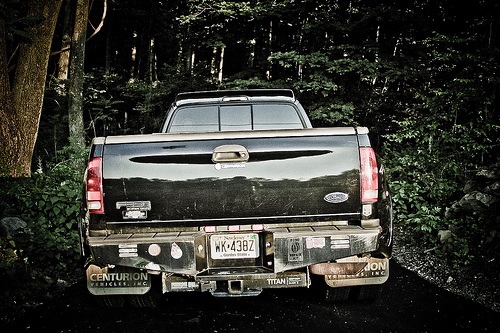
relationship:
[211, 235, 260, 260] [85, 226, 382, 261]
license plate on bumper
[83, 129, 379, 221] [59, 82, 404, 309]
tailgate on truck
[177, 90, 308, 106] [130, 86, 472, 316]
rack on top of truck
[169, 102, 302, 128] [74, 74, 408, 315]
back window on ford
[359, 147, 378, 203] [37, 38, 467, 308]
brake light on truck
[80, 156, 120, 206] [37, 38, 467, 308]
brake light on truck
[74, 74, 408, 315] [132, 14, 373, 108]
ford in woods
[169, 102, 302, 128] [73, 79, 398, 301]
back window of truck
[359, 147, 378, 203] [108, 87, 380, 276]
brake light of truck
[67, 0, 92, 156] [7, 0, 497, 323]
tree in forest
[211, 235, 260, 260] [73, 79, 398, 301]
license plate on truck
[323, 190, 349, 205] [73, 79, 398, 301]
logo on truck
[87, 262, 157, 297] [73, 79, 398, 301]
sticker on truck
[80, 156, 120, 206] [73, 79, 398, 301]
brake light on truck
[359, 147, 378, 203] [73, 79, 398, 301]
brake light on truck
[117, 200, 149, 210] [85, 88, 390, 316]
name on truck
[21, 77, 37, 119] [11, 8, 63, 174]
bark on side of tree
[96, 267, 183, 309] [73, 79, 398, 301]
tire of truck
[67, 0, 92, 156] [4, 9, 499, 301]
tree in woods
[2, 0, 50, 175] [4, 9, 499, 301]
tree in woods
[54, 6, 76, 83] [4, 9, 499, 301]
tree in woods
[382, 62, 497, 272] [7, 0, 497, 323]
tree in forest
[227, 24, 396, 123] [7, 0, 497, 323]
tree in forest